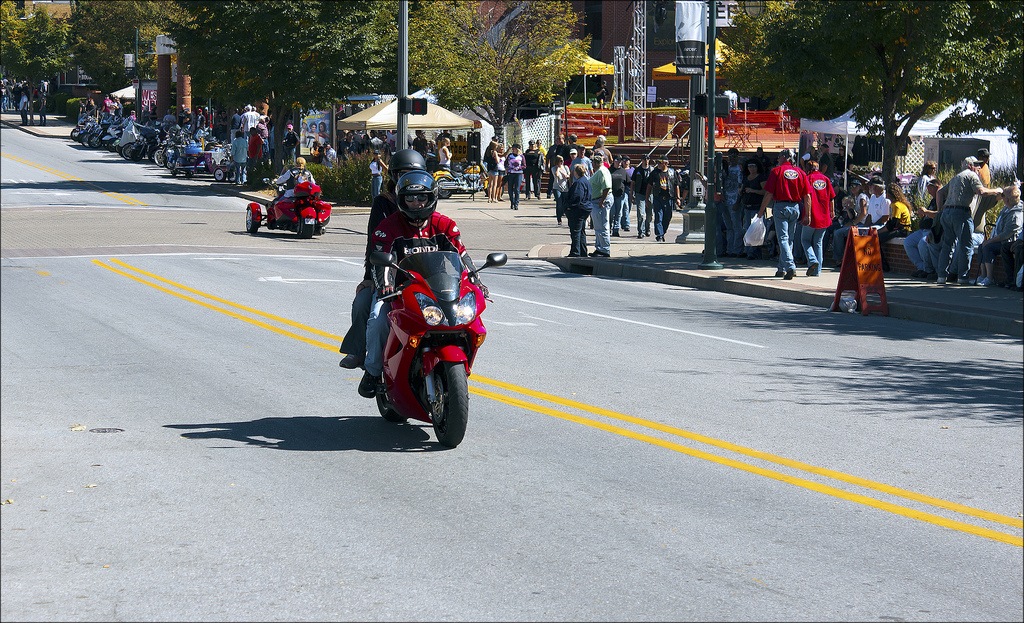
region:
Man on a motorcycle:
[361, 160, 499, 454]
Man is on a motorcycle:
[362, 160, 505, 454]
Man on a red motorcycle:
[367, 168, 505, 453]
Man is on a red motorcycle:
[354, 165, 523, 444]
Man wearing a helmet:
[389, 166, 444, 230]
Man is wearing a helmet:
[393, 160, 450, 227]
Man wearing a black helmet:
[387, 162, 439, 229]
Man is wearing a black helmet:
[392, 163, 450, 225]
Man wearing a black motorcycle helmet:
[380, 162, 457, 242]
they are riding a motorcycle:
[318, 100, 571, 487]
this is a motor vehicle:
[236, 145, 345, 259]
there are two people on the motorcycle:
[321, 121, 553, 454]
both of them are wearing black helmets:
[311, 110, 545, 464]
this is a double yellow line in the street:
[105, 243, 1020, 604]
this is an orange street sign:
[825, 212, 905, 333]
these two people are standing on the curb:
[541, 132, 650, 266]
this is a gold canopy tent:
[320, 76, 504, 212]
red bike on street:
[390, 217, 495, 413]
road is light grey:
[488, 458, 748, 611]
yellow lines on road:
[698, 450, 949, 581]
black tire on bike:
[382, 330, 500, 454]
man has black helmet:
[386, 158, 462, 226]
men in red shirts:
[766, 169, 836, 268]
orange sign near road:
[828, 210, 886, 327]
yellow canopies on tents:
[459, 49, 755, 103]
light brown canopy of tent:
[342, 107, 483, 142]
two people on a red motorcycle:
[331, 110, 518, 519]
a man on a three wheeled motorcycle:
[242, 121, 342, 261]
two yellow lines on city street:
[670, 402, 994, 555]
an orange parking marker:
[827, 214, 905, 336]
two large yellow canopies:
[518, 31, 782, 90]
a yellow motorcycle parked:
[438, 154, 505, 200]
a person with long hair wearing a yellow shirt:
[884, 179, 927, 244]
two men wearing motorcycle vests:
[631, 149, 686, 206]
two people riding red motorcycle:
[337, 142, 506, 449]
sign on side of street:
[824, 222, 901, 320]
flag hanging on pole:
[672, 2, 721, 80]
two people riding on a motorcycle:
[334, 138, 508, 451]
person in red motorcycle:
[238, 146, 337, 241]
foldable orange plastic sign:
[820, 220, 891, 319]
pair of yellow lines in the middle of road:
[90, 247, 1021, 543]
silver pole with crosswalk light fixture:
[387, 2, 426, 152]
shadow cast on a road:
[159, 408, 442, 460]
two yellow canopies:
[528, 29, 757, 105]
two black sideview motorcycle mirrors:
[364, 240, 511, 283]